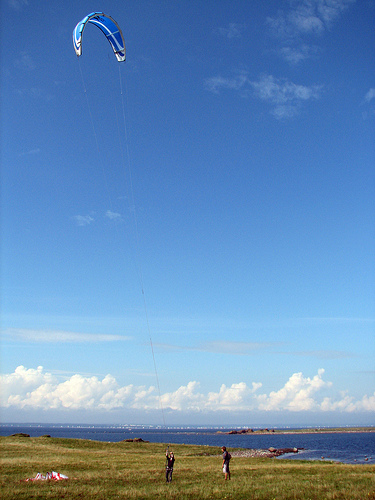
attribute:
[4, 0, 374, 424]
sky — blue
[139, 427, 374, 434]
field — open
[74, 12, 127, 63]
kite — red and white, blue and white, large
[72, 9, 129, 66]
kite — large, blue and white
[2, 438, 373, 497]
field — grassy, large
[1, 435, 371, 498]
grass — green and brown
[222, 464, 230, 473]
shorts — white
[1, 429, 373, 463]
water — blue, waveless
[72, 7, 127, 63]
kite — large, blue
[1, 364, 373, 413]
clouds — white, puffy, fluffy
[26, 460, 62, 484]
kite — RED, WHITE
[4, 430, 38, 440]
rocks — LARGE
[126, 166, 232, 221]
sky — BLUE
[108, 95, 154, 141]
sky — BLUE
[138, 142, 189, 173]
sky — MANY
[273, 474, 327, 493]
grass — GREEN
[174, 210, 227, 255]
sky — BLUE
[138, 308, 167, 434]
string — KITE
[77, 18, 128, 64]
kite — LARGE, CURVED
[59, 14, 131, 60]
kite — RED, WHITE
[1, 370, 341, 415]
clouds — ROW, WHITE, PUFFY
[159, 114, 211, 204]
sky — BRILLIANT, BLUE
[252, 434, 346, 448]
water — LARGE, EXPANSE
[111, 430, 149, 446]
rock — LARGE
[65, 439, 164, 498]
grass — green, drying